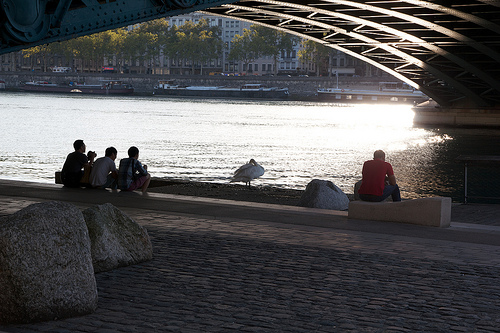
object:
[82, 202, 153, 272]
rock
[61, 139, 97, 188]
boy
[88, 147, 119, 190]
boy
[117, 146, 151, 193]
boy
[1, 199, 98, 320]
rock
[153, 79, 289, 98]
boat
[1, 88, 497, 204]
river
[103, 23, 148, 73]
building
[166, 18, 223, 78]
tree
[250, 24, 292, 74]
tree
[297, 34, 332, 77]
tree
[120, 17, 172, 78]
tree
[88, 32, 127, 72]
tree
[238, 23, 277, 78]
building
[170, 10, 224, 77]
building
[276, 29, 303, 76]
building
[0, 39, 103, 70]
building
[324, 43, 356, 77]
building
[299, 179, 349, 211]
rock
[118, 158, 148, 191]
shirt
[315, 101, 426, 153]
reflection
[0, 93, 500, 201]
water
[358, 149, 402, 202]
man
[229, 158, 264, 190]
bird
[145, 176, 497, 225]
edge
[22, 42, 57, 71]
trees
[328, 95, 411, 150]
sunlight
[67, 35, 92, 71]
trees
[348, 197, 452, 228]
block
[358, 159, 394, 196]
shirt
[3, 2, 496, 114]
bridge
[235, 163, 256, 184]
back